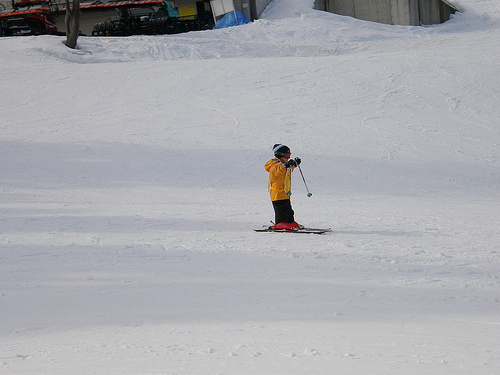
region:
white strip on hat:
[273, 146, 284, 151]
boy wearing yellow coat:
[273, 174, 281, 189]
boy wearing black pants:
[276, 204, 286, 216]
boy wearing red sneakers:
[271, 222, 296, 231]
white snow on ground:
[193, 289, 298, 357]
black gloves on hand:
[287, 162, 294, 167]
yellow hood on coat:
[266, 161, 273, 171]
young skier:
[258, 141, 322, 253]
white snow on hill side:
[48, 245, 100, 302]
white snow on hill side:
[371, 226, 421, 280]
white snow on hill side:
[254, 289, 281, 331]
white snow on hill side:
[95, 236, 146, 291]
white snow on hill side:
[115, 155, 179, 225]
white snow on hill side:
[48, 176, 108, 253]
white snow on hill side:
[292, 48, 360, 109]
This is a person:
[246, 128, 356, 263]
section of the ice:
[29, 283, 132, 370]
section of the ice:
[82, 158, 215, 282]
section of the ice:
[335, 244, 420, 361]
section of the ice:
[38, 72, 139, 184]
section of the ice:
[319, 54, 446, 192]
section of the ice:
[102, 48, 222, 190]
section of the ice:
[59, 128, 133, 310]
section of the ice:
[70, 276, 275, 373]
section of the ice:
[353, 198, 482, 358]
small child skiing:
[259, 140, 334, 238]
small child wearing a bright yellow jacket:
[259, 157, 299, 203]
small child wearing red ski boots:
[270, 216, 297, 235]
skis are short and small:
[256, 220, 336, 240]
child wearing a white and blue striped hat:
[269, 137, 291, 161]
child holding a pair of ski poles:
[281, 157, 313, 200]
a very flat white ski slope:
[1, 17, 498, 369]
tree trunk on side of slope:
[59, 0, 84, 53]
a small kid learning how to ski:
[254, 139, 334, 241]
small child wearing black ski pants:
[270, 191, 297, 228]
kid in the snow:
[203, 118, 343, 263]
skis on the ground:
[239, 208, 336, 265]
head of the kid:
[259, 133, 304, 170]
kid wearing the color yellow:
[238, 140, 314, 214]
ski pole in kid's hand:
[295, 162, 324, 202]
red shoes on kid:
[262, 210, 316, 240]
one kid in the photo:
[223, 115, 365, 251]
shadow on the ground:
[77, 164, 211, 281]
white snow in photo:
[62, 144, 210, 289]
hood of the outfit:
[248, 153, 282, 186]